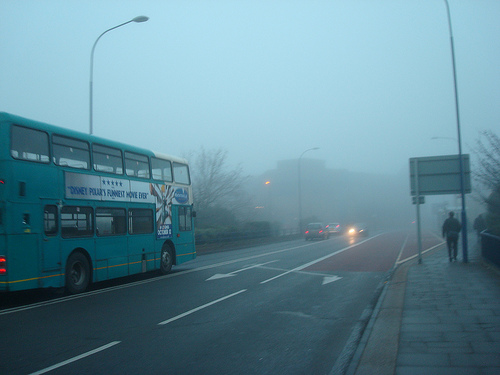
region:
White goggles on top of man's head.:
[343, 365, 351, 372]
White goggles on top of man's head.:
[256, 363, 260, 371]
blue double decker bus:
[3, 105, 208, 312]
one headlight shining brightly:
[346, 225, 358, 237]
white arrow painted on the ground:
[196, 253, 284, 282]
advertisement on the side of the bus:
[56, 162, 201, 247]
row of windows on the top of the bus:
[8, 122, 198, 185]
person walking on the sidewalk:
[439, 203, 466, 265]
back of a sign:
[403, 155, 477, 196]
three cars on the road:
[291, 210, 383, 247]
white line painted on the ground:
[14, 338, 129, 373]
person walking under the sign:
[403, 148, 486, 271]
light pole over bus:
[70, 7, 137, 124]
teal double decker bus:
[5, 119, 188, 284]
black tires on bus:
[38, 232, 184, 287]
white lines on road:
[38, 287, 250, 374]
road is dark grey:
[219, 305, 336, 369]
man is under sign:
[427, 155, 484, 270]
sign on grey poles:
[395, 156, 473, 271]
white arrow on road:
[199, 235, 282, 293]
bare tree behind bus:
[181, 153, 272, 226]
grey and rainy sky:
[172, 10, 307, 106]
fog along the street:
[199, 158, 420, 258]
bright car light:
[347, 218, 354, 248]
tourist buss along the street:
[1, 134, 168, 286]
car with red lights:
[293, 223, 349, 258]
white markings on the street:
[46, 287, 416, 354]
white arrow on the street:
[198, 265, 275, 288]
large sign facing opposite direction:
[385, 142, 474, 209]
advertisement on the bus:
[49, 172, 188, 209]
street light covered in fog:
[270, 139, 323, 219]